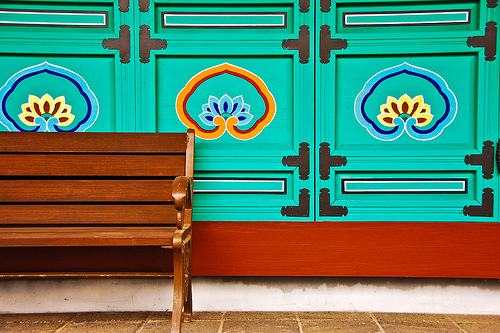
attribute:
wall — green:
[0, 2, 499, 279]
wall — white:
[268, 267, 492, 315]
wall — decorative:
[0, 5, 497, 210]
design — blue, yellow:
[339, 54, 484, 145]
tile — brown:
[364, 304, 468, 331]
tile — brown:
[283, 302, 383, 332]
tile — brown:
[213, 307, 315, 331]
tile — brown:
[52, 319, 155, 331]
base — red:
[194, 227, 499, 263]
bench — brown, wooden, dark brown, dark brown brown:
[0, 127, 194, 331]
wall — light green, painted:
[216, 52, 398, 148]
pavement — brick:
[0, 308, 498, 330]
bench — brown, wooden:
[19, 107, 216, 304]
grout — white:
[10, 323, 496, 324]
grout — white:
[448, 313, 462, 331]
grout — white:
[372, 313, 384, 331]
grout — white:
[293, 313, 302, 332]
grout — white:
[219, 312, 225, 332]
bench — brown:
[0, 119, 223, 305]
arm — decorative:
[170, 174, 190, 244]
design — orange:
[173, 61, 276, 141]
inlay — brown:
[281, 24, 348, 63]